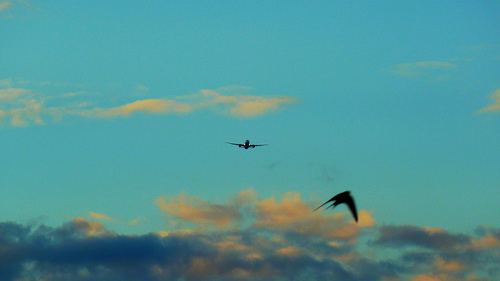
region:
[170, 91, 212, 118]
part of a cloud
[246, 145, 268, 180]
part of a plane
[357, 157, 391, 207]
part of a the sky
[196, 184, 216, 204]
part of a cloud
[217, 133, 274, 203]
part of a cloud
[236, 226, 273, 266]
part of a cloud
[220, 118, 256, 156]
part of a plane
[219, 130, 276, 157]
a plane flying in the sky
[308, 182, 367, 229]
a bird in the sky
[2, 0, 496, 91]
part of the sky color turquoise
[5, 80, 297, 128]
part of the sky with white clouds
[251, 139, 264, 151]
right wing of plane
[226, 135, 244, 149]
left wing of plane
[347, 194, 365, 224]
right wing of bird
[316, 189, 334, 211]
left wing of bird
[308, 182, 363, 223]
bird is color black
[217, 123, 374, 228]
a bird and a plane flying in the same direction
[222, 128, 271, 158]
airplane flying in the sky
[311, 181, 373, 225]
bird in the sky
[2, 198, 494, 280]
clouds in the sky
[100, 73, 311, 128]
thin cloud in the sky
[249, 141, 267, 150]
thin wing on the side of the plane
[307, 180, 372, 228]
silhouette of a bird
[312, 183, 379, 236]
bird flying by the clouds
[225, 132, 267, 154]
silhouette of a plane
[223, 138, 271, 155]
two wings on the plane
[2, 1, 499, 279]
bright blue sky with clouds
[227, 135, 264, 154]
airplane flying through the sky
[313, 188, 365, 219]
bird flying through the sky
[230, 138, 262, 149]
wings of the airplane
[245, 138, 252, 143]
nose of the airplane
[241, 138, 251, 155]
underside of the airplane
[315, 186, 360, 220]
bird flapping his wings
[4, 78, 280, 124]
white clouds in the blue sky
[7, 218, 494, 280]
dark gray clouds in the sky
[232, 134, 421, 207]
bird and airplane flying through the sky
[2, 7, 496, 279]
blue sky bird and plane are flying in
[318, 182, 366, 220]
this is a bird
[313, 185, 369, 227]
the bird is on air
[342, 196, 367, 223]
this is the wing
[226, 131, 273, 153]
this is a plane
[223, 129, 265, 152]
the plane is on air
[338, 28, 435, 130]
this is the sky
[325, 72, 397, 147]
the sky is blue in color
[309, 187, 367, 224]
the bird is black in color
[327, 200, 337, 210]
this is the tail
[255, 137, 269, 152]
this is the wing